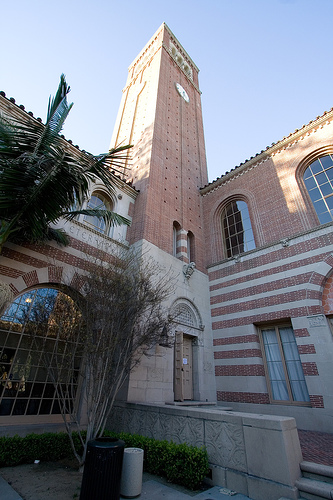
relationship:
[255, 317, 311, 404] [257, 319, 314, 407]
window has trim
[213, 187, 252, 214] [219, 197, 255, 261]
half circle above window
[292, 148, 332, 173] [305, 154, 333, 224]
half circle above window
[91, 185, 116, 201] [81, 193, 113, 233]
half circle above window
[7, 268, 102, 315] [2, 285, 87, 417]
half circle above window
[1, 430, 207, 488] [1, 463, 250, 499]
hedge row next to street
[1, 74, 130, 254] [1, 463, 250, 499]
palm tree near street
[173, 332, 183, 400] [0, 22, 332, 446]
door on building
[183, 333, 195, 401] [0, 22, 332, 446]
door on building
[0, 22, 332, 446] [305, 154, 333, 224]
building has window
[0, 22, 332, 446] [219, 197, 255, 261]
building has window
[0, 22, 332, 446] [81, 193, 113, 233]
building has window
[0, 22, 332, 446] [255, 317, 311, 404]
building has window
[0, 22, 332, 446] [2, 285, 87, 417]
building has window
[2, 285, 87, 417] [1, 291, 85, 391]
window has reflection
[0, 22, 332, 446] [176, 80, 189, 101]
building has clock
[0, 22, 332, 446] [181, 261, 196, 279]
building has statue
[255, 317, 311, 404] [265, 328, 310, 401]
window has curtain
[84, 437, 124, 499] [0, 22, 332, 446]
trash can outside building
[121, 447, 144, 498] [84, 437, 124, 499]
ash tray next to trash can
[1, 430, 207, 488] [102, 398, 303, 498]
hedge row next to wall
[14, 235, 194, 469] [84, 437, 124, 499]
tree next to trash can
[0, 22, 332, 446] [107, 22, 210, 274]
building has tower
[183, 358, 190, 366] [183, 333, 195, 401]
paper on door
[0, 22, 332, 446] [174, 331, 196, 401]
building has doorway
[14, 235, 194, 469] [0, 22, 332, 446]
tree next to building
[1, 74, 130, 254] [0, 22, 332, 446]
palm tree next to building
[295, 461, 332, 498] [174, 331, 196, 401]
stairs near doorway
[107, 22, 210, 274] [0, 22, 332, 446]
tower on building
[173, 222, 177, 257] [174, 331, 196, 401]
window above doorway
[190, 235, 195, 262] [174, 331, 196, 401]
window above doorway